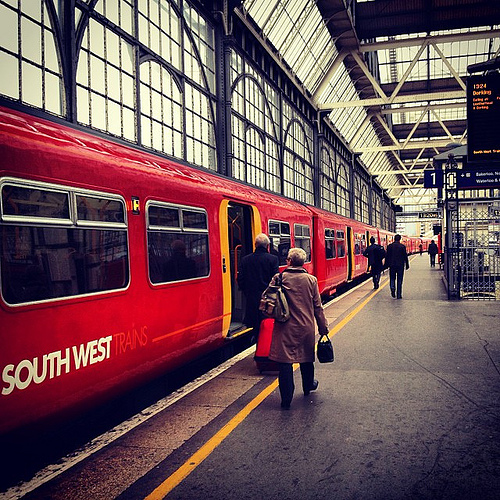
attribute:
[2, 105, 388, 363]
train — red, stopping, here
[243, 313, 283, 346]
shopping bag — red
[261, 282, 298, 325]
backpack — grey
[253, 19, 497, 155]
ceiling — glass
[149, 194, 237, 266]
window — silver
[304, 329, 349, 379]
handbag — black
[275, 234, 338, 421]
woman — old, walkig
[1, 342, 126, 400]
lettering — red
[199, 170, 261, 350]
door — tellow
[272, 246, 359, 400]
lady — old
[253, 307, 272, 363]
bag — here, red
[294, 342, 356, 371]
bag — black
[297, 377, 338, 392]
shoe — black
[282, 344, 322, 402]
pants — black